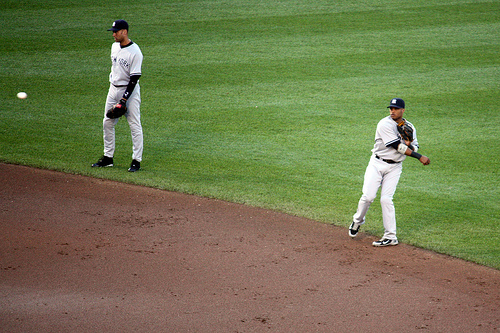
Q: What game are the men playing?
A: Baseball.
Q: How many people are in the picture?
A: Two.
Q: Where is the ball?
A: To the left.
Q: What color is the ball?
A: White.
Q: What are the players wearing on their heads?
A: Caps.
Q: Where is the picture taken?
A: Baseball field.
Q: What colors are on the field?
A: Green and brown.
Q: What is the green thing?
A: Grass.